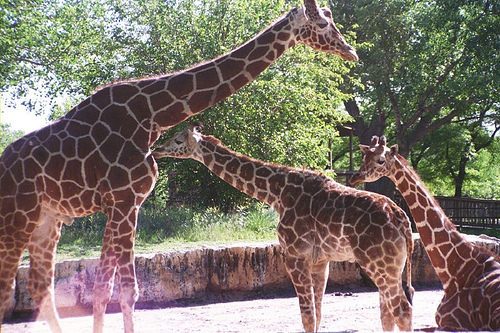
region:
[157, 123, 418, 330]
A young giraffe nuzzling an older one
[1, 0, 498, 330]
Three giraffes in an enclosure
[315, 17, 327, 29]
An eye on a giraffe's face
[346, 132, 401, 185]
The head of a young giraffe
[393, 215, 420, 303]
A tail on a young giraffe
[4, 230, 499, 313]
A rock wall around an enclosure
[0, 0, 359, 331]
a mother giraffe with her babies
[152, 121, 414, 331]
baby giraffe with its nose on its mom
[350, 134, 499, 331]
baby giraffe sitting next to its sibling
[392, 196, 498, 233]
a wooden picket fence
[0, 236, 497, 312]
low stone embankment inside enclosure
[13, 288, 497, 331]
dirt floor of giraffe enclosure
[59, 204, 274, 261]
grassy area with tall weeds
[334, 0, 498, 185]
tall old leafy tree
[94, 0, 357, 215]
large overgrown bush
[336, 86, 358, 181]
gazebo mostly hidden in the trees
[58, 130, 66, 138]
brown spot on giraffe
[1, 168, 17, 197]
brown spot on giraffe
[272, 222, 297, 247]
brown spot on giraffe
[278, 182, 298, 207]
brown spot on giraffe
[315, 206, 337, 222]
brown spot on giraffe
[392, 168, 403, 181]
brown spot on giraffe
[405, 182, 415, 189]
brown spot on giraffe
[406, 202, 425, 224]
brown spot on giraffe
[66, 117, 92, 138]
brown spot on giraffe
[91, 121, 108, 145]
brown spot on giraffe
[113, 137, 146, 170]
brown spot on giraffe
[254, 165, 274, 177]
brown spot on giraffe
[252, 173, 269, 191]
brown spot on giraffe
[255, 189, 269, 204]
brown spot on giraffe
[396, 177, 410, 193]
brown spot on giraffe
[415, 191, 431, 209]
brown spot on giraffe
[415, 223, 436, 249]
brown spot on giraffe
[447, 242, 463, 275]
brown spot on giraffe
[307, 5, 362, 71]
face of a giraffe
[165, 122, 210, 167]
face of a giraffe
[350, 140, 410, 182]
face of a giraffe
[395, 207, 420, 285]
tail of a giraffe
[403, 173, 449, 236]
neck of a giraffe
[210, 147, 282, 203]
neck of a giraffe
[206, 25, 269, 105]
neck of a giraffe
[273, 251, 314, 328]
leg of a griaffe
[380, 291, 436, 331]
legs of a giraffe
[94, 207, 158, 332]
legs of a giraffe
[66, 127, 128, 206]
Brown and white patches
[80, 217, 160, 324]
Long legs of a giraffe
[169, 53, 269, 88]
Long neck of a giraffe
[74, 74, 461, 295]
Three giraffes in the field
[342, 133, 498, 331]
small giraffe facing left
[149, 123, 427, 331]
middle giraffe facing left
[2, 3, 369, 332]
tall giraffe facing right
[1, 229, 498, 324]
low stone wall behind giraffes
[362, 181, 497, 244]
low fence behind giraffes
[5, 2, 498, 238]
leafy green trees behind giraffes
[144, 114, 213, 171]
giraffe head reaching forward